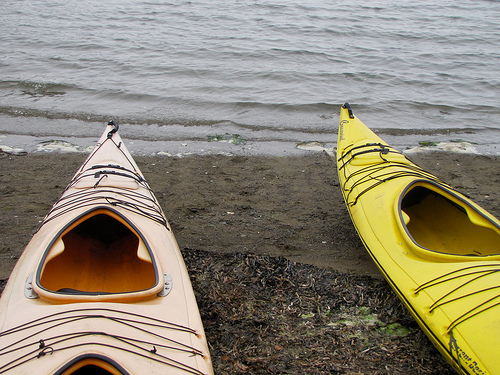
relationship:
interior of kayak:
[50, 210, 157, 293] [3, 100, 235, 372]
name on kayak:
[335, 112, 348, 150] [333, 128, 494, 333]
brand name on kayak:
[445, 329, 479, 373] [333, 128, 494, 333]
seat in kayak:
[58, 283, 118, 302] [3, 100, 235, 372]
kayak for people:
[3, 100, 235, 372] [26, 190, 173, 372]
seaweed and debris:
[193, 245, 456, 368] [185, 242, 453, 372]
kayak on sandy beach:
[333, 128, 494, 333] [3, 98, 481, 370]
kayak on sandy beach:
[3, 100, 235, 372] [3, 98, 481, 370]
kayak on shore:
[333, 128, 494, 333] [1, 144, 484, 373]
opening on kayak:
[392, 175, 483, 261] [333, 128, 494, 333]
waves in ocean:
[192, 33, 434, 84] [1, 1, 484, 162]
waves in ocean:
[5, 90, 296, 137] [1, 1, 484, 162]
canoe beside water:
[338, 106, 498, 373] [6, 3, 496, 165]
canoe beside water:
[0, 120, 212, 372] [6, 3, 496, 165]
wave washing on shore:
[1, 127, 334, 143] [1, 144, 484, 373]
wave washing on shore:
[1, 103, 484, 134] [1, 144, 484, 373]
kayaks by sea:
[4, 117, 217, 373] [5, 5, 497, 169]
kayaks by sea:
[334, 100, 497, 369] [5, 5, 497, 169]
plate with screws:
[154, 270, 172, 299] [157, 268, 171, 295]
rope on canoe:
[0, 303, 209, 373] [0, 120, 212, 372]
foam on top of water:
[27, 132, 67, 153] [154, 34, 368, 117]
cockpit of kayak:
[395, 172, 484, 264] [333, 128, 494, 333]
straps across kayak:
[37, 183, 167, 228] [3, 100, 235, 372]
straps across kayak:
[340, 161, 440, 209] [333, 128, 494, 333]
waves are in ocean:
[192, 33, 434, 84] [1, 1, 484, 162]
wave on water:
[1, 127, 334, 143] [6, 3, 496, 165]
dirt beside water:
[213, 187, 339, 362] [6, 3, 496, 165]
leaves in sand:
[227, 277, 401, 349] [200, 192, 350, 367]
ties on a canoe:
[52, 151, 187, 220] [9, 86, 209, 354]